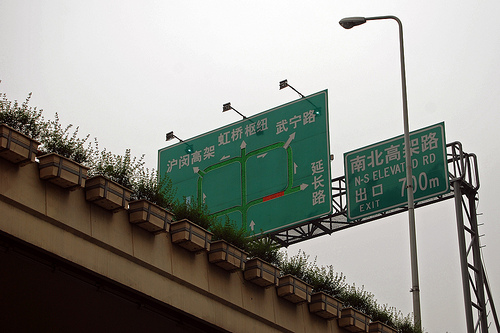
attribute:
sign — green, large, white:
[153, 90, 333, 233]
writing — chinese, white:
[159, 107, 316, 173]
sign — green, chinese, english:
[342, 120, 449, 220]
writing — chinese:
[349, 130, 439, 171]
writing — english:
[352, 154, 435, 190]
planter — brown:
[0, 121, 40, 169]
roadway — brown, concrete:
[0, 130, 415, 332]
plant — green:
[0, 84, 44, 135]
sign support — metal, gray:
[264, 141, 498, 332]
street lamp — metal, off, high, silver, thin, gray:
[338, 14, 425, 332]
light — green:
[309, 103, 325, 118]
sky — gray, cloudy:
[0, 0, 496, 332]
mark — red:
[261, 189, 285, 203]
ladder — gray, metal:
[448, 139, 498, 333]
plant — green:
[42, 112, 94, 163]